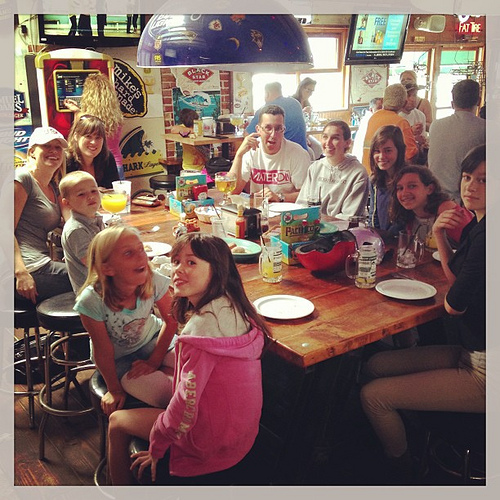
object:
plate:
[375, 277, 438, 300]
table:
[92, 188, 446, 368]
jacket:
[147, 293, 266, 477]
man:
[227, 103, 312, 204]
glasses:
[256, 123, 287, 135]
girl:
[106, 229, 275, 484]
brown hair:
[166, 231, 274, 353]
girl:
[71, 220, 181, 417]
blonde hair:
[74, 226, 157, 313]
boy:
[58, 169, 106, 298]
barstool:
[35, 289, 98, 463]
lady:
[368, 124, 414, 236]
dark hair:
[367, 123, 408, 193]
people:
[386, 164, 478, 250]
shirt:
[240, 136, 310, 196]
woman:
[14, 124, 75, 313]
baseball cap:
[28, 126, 68, 150]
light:
[135, 9, 315, 76]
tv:
[344, 14, 411, 67]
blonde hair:
[79, 72, 126, 140]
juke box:
[32, 46, 116, 138]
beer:
[215, 181, 236, 192]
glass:
[214, 172, 238, 207]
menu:
[280, 205, 321, 245]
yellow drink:
[101, 194, 127, 215]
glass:
[99, 191, 128, 224]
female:
[358, 141, 486, 485]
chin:
[463, 200, 484, 212]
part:
[295, 346, 334, 380]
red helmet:
[295, 228, 358, 276]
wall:
[312, 12, 353, 27]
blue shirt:
[72, 271, 172, 363]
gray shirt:
[60, 208, 107, 295]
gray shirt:
[13, 166, 62, 273]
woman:
[295, 119, 369, 220]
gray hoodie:
[294, 153, 370, 222]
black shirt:
[445, 214, 485, 354]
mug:
[344, 244, 379, 290]